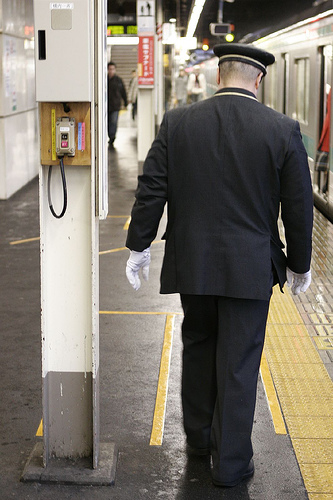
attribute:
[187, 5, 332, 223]
train — subway, metro, silver, waiting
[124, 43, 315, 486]
conductor — walking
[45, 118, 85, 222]
telephone — conductor's, metro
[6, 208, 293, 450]
markings — yellow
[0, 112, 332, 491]
platform — subway, grey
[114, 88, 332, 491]
suit — black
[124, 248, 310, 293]
gloves — white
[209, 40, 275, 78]
hat — conductor's, black, captain's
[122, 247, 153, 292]
glove — white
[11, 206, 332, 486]
zone — painted, warning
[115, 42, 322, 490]
employee — railway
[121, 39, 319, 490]
uniform — black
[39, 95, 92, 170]
box — electrical, mounted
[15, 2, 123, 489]
post — white, grey, support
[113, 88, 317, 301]
jacket — black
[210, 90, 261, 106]
trim — gold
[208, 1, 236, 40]
camera — mounted, security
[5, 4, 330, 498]
tunnel — subway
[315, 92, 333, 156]
jacket — red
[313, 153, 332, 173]
skirt — plaid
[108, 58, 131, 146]
person — walking, entering, leaving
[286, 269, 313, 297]
glove — white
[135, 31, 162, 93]
sign — red, white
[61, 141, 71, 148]
button — red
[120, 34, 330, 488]
man — dressed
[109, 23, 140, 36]
sign — yellow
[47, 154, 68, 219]
cord — black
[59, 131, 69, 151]
switch — red, black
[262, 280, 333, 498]
strip — yellow, slip resisitant